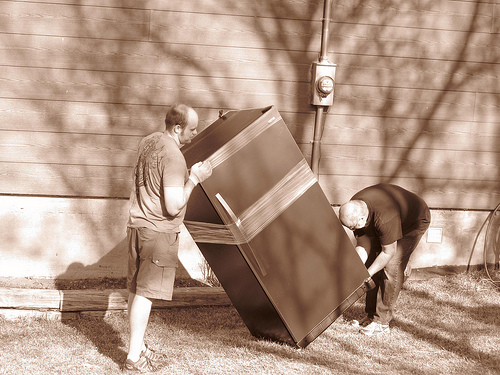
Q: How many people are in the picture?
A: Two.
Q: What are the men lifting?
A: Refrigerator.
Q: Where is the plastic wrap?
A: The fridge.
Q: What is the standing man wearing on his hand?
A: Glove.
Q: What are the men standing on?
A: Grass.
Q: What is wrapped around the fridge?
A: Plastic.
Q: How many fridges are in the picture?
A: One.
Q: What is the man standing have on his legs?
A: Shorts.